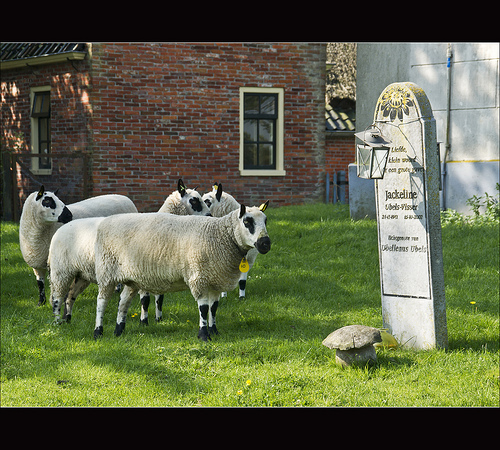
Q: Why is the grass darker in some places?
A: Shadows.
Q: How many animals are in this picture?
A: Four.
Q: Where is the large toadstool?
A: In front of the tombstone.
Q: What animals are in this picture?
A: Sheep.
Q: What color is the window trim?
A: White.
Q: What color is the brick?
A: Red.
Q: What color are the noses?
A: Black.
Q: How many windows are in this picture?
A: Two.